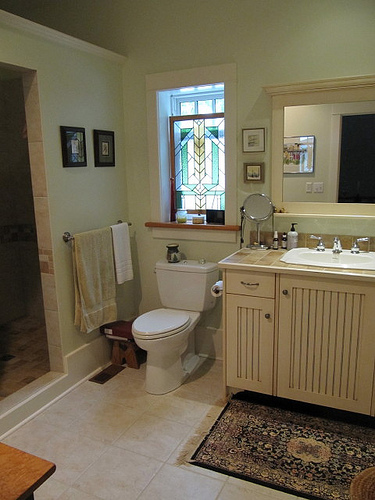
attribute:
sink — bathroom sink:
[280, 245, 374, 268]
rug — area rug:
[184, 392, 372, 498]